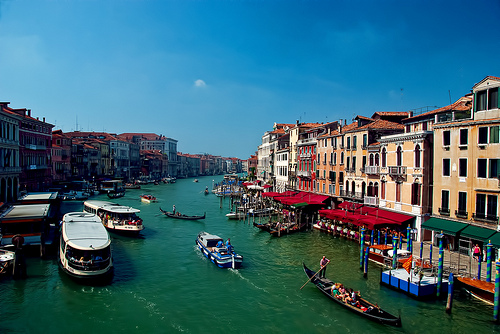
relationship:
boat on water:
[192, 232, 245, 270] [3, 165, 497, 328]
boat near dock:
[380, 262, 442, 301] [391, 238, 493, 288]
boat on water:
[55, 211, 114, 287] [3, 165, 497, 328]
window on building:
[439, 130, 452, 147] [428, 120, 476, 240]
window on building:
[457, 123, 470, 149] [428, 120, 484, 243]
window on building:
[469, 130, 485, 147] [423, 107, 483, 258]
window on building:
[478, 130, 485, 144] [430, 120, 484, 298]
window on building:
[440, 155, 452, 177] [421, 114, 482, 248]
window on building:
[457, 158, 467, 177] [428, 122, 485, 255]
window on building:
[472, 160, 484, 180] [425, 128, 480, 246]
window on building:
[437, 189, 452, 214] [425, 118, 484, 257]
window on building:
[477, 132, 485, 138] [420, 122, 484, 239]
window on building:
[472, 86, 483, 108] [433, 80, 483, 226]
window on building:
[440, 159, 452, 178] [232, 81, 477, 266]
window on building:
[454, 121, 471, 152] [426, 112, 484, 232]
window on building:
[477, 127, 489, 146] [245, 63, 482, 231]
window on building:
[475, 123, 484, 136] [248, 61, 484, 277]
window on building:
[474, 158, 481, 171] [238, 74, 484, 275]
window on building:
[474, 156, 488, 180] [238, 74, 484, 275]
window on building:
[440, 159, 452, 178] [238, 74, 484, 275]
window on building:
[470, 85, 484, 109] [415, 50, 484, 236]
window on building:
[472, 88, 488, 110] [428, 65, 484, 246]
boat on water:
[55, 211, 114, 287] [50, 179, 308, 331]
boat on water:
[158, 206, 206, 220] [112, 175, 270, 332]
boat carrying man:
[300, 261, 406, 329] [319, 255, 330, 278]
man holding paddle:
[317, 253, 332, 277] [295, 258, 329, 291]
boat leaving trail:
[184, 223, 251, 266] [213, 260, 278, 299]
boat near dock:
[300, 261, 406, 329] [359, 214, 476, 304]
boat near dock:
[298, 258, 405, 328] [367, 235, 477, 322]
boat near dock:
[46, 203, 129, 292] [1, 184, 61, 273]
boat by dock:
[153, 201, 273, 283] [211, 171, 335, 231]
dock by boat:
[266, 172, 441, 280] [182, 220, 277, 283]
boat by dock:
[55, 211, 114, 287] [8, 186, 80, 275]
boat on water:
[158, 206, 206, 220] [146, 189, 296, 308]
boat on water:
[300, 261, 406, 329] [185, 234, 435, 321]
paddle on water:
[287, 245, 344, 291] [127, 212, 367, 326]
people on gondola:
[326, 276, 373, 308] [277, 250, 415, 331]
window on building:
[457, 158, 467, 177] [430, 76, 499, 253]